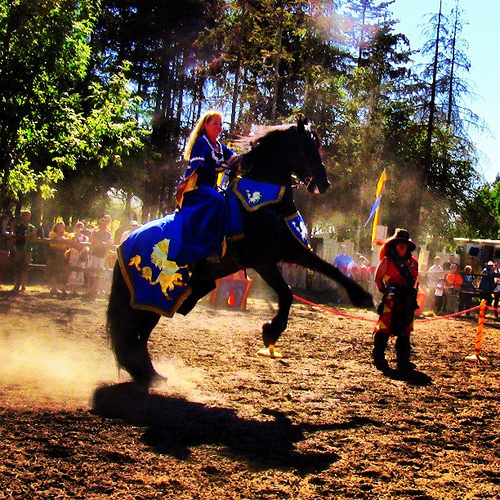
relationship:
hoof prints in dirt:
[347, 381, 449, 471] [1, 286, 498, 487]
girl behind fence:
[166, 109, 239, 267] [5, 222, 177, 299]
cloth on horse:
[108, 205, 208, 319] [91, 96, 380, 380]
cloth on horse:
[231, 170, 290, 215] [91, 96, 380, 380]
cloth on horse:
[279, 200, 319, 257] [91, 96, 380, 380]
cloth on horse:
[115, 205, 207, 318] [77, 75, 374, 320]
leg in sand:
[254, 263, 316, 354] [72, 332, 319, 463]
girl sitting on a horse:
[174, 95, 241, 193] [74, 100, 403, 398]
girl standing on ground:
[373, 227, 418, 371] [4, 302, 499, 497]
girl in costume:
[166, 109, 239, 267] [157, 133, 237, 262]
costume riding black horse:
[157, 133, 237, 262] [106, 113, 375, 399]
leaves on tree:
[3, 0, 150, 206] [3, 0, 138, 214]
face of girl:
[205, 111, 225, 141] [171, 111, 236, 292]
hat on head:
[384, 229, 419, 248] [396, 243, 408, 253]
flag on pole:
[364, 167, 386, 227] [354, 161, 409, 305]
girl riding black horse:
[166, 109, 239, 267] [106, 119, 378, 398]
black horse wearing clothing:
[106, 113, 375, 399] [117, 176, 284, 312]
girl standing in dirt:
[371, 227, 420, 371] [336, 418, 376, 450]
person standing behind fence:
[63, 215, 88, 293] [19, 234, 118, 291]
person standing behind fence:
[331, 241, 349, 268] [0, 225, 499, 322]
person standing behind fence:
[10, 209, 35, 293] [0, 225, 499, 322]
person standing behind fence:
[46, 219, 66, 289] [0, 225, 499, 322]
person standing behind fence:
[90, 217, 110, 283] [0, 225, 499, 322]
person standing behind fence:
[423, 254, 444, 309] [0, 225, 499, 322]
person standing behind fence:
[455, 262, 479, 322] [420, 282, 496, 321]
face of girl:
[207, 115, 223, 134] [162, 104, 249, 274]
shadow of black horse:
[88, 383, 382, 477] [106, 113, 375, 399]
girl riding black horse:
[166, 109, 239, 267] [106, 113, 375, 399]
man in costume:
[370, 230, 417, 376] [372, 230, 417, 378]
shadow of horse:
[88, 383, 382, 477] [91, 96, 380, 380]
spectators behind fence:
[3, 206, 498, 310] [23, 235, 495, 306]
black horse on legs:
[106, 113, 375, 399] [86, 267, 183, 409]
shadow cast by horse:
[88, 383, 382, 477] [106, 112, 373, 385]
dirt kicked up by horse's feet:
[1, 286, 498, 487] [113, 312, 168, 386]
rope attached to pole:
[231, 258, 498, 370] [473, 292, 491, 352]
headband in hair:
[198, 108, 213, 124] [181, 110, 226, 161]